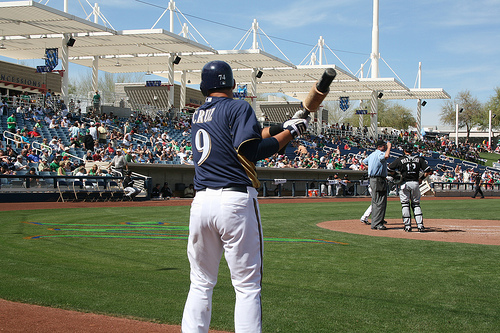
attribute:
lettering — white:
[189, 105, 220, 134]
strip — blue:
[245, 194, 275, 331]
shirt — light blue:
[362, 146, 393, 187]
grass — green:
[7, 189, 496, 324]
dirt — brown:
[2, 298, 209, 330]